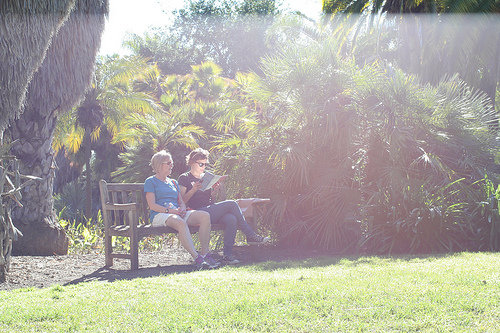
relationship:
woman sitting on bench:
[142, 149, 221, 270] [93, 177, 273, 274]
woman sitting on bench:
[177, 147, 272, 265] [93, 177, 273, 274]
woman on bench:
[142, 149, 221, 270] [97, 178, 259, 272]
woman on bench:
[177, 146, 266, 266] [97, 178, 259, 272]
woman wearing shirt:
[142, 149, 221, 270] [143, 180, 192, 214]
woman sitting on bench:
[142, 149, 221, 270] [101, 171, 260, 267]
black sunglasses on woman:
[192, 158, 210, 169] [177, 146, 266, 266]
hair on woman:
[184, 146, 209, 176] [177, 146, 266, 266]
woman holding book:
[177, 147, 272, 265] [197, 170, 228, 193]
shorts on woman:
[154, 210, 194, 226] [147, 150, 212, 265]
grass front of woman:
[4, 252, 497, 331] [142, 149, 221, 270]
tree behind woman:
[0, 1, 76, 271] [183, 143, 267, 259]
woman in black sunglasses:
[177, 147, 272, 265] [189, 159, 210, 168]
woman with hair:
[177, 147, 272, 265] [187, 149, 207, 164]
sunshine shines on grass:
[35, 6, 457, 190] [4, 252, 497, 331]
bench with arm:
[94, 172, 240, 273] [107, 200, 139, 270]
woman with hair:
[142, 149, 221, 270] [149, 150, 174, 175]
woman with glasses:
[142, 149, 221, 270] [161, 159, 171, 166]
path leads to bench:
[3, 252, 227, 282] [86, 176, 267, 263]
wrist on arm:
[159, 207, 176, 217] [140, 176, 180, 216]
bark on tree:
[34, 47, 90, 209] [11, 5, 140, 285]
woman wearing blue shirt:
[142, 149, 221, 270] [144, 175, 181, 222]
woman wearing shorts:
[142, 149, 221, 270] [151, 209, 199, 227]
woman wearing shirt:
[177, 147, 272, 265] [179, 170, 216, 208]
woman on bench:
[177, 147, 272, 265] [86, 176, 267, 263]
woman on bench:
[142, 149, 221, 270] [86, 176, 267, 263]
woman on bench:
[177, 147, 272, 265] [99, 174, 266, 270]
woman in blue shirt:
[142, 149, 221, 270] [143, 174, 182, 227]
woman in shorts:
[142, 149, 221, 270] [150, 209, 197, 224]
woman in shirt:
[177, 146, 266, 266] [179, 170, 210, 209]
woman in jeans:
[177, 146, 266, 266] [200, 200, 260, 257]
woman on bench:
[177, 147, 272, 265] [81, 177, 292, 274]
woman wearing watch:
[142, 149, 221, 270] [162, 205, 172, 214]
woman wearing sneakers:
[142, 149, 218, 271] [195, 252, 222, 270]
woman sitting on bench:
[142, 149, 218, 271] [99, 174, 266, 270]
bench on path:
[97, 178, 259, 272] [0, 239, 336, 290]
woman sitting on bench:
[177, 147, 272, 265] [93, 157, 266, 271]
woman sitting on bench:
[142, 149, 218, 271] [93, 157, 266, 271]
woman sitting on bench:
[142, 149, 218, 271] [99, 176, 200, 271]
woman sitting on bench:
[177, 146, 266, 266] [99, 176, 200, 271]